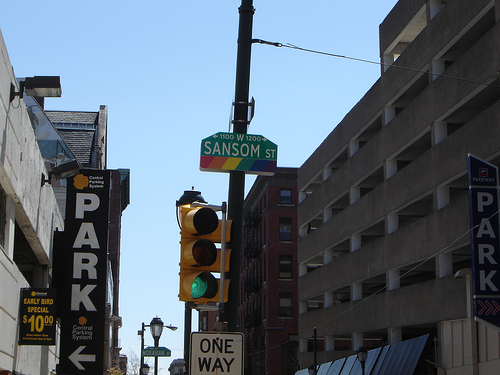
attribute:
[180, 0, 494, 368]
building — tall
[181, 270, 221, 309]
signal — green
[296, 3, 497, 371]
garage — large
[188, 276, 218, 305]
light — green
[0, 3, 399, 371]
sky — blue, clear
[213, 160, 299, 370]
building — bricked, red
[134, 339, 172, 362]
base — black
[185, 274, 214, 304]
light — green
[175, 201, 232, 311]
stoplight — lit, green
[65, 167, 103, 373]
sign — parking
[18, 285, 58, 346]
sign — parking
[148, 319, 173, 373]
lamp — street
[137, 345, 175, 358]
sign — street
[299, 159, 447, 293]
garage — cement, parking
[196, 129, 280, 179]
sign — street, Sansom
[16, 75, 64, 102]
light — flood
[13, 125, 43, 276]
garage — side, parking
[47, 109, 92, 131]
roof — building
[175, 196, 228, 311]
stoplight — yellow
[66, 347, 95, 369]
arrow — white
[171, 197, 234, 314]
light — stop, green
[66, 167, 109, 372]
sign — parking, colored, black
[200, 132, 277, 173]
sign — street, colored, green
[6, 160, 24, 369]
area — parking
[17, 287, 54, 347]
sign — ten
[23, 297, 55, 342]
special — dollars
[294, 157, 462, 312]
structure — parking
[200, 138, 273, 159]
name — Sansom, Street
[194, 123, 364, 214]
sign — rainbow colored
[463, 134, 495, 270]
sign — linear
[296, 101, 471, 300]
garage — large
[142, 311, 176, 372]
light — black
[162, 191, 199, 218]
light — black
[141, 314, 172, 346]
light — black